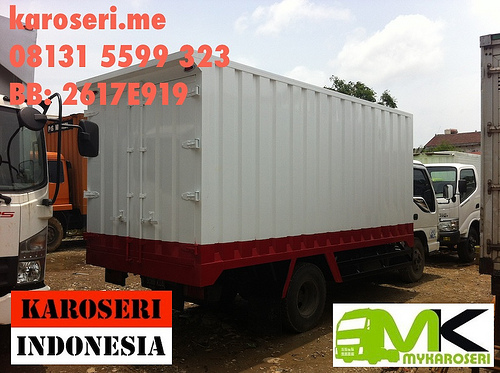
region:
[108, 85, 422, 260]
a big white storage box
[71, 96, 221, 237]
the back of a storage pod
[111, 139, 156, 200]
the latches of a storage pod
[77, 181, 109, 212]
the hinges of a storage pod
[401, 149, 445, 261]
the front of a moving truck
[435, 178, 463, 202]
the mirror of a moving truck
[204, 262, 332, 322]
the wheels of a moving truck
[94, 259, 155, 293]
the mud flaps of a moving truck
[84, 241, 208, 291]
the bumper of a moving truck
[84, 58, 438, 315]
the truck is parked in the lot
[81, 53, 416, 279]
the container is white in color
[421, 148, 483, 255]
the truck is white in color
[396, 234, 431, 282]
the tire is made of rubber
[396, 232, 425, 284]
the tire is black in color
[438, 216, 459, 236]
the bumper is on the front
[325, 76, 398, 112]
a tree is on the background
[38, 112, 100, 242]
a truck is on the background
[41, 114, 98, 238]
the truck is red in color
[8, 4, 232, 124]
lettering is on the picture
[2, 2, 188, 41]
this is a website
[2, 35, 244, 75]
this is a phone number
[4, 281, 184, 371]
the letters are black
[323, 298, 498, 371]
this is a logo for a company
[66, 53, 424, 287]
this storage trailer is white and red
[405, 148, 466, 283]
the truck cab is white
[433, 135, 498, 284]
this truck is white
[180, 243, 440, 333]
the wheels are covered in the shadows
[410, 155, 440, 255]
this is the door and a window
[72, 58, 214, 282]
the trailer is closed shut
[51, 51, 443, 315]
truck in a lot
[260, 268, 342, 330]
rear tire on the truck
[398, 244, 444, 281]
front tire on the truck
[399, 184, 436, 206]
window on the truck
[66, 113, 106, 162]
mirror on the truck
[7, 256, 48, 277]
light on the truck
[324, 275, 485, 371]
graphic and lettering on image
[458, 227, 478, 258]
front tire on the truck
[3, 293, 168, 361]
branding information on image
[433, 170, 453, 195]
window on the truck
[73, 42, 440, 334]
a white and red truck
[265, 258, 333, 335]
the tire of a truck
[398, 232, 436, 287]
the tire of a truck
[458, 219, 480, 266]
the tire of a truck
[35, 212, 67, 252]
the tire of a truck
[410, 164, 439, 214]
the window of a truck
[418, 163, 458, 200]
the windshield of a truck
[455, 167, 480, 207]
the window of a truck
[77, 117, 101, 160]
a side mirror for a truck